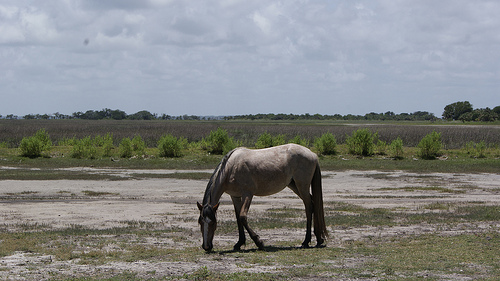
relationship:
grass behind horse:
[37, 146, 460, 175] [196, 144, 328, 252]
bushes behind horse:
[17, 132, 445, 156] [196, 144, 328, 252]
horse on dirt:
[196, 144, 328, 252] [119, 171, 411, 244]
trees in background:
[76, 108, 151, 123] [23, 71, 480, 132]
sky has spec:
[49, 9, 403, 100] [80, 37, 91, 44]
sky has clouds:
[49, 9, 403, 100] [166, 20, 284, 63]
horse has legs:
[196, 144, 328, 252] [230, 193, 265, 250]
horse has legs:
[196, 144, 328, 252] [296, 189, 323, 251]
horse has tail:
[196, 144, 328, 252] [310, 168, 335, 246]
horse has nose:
[196, 144, 328, 252] [201, 222, 216, 248]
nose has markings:
[201, 222, 216, 248] [203, 222, 207, 240]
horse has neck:
[196, 144, 328, 252] [206, 175, 221, 212]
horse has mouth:
[196, 144, 328, 252] [202, 241, 216, 252]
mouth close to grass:
[202, 241, 216, 252] [37, 146, 460, 175]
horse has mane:
[196, 144, 328, 252] [213, 160, 223, 206]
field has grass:
[18, 121, 498, 167] [37, 146, 460, 175]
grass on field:
[37, 146, 460, 175] [18, 121, 498, 167]